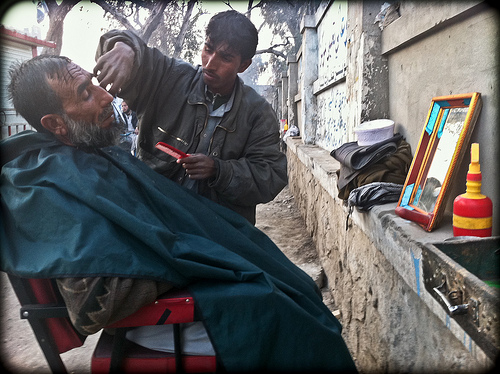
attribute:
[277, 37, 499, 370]
wall — concrete, brick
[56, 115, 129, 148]
beard — gray, black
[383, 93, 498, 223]
mirror — blue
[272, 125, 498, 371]
wall — stone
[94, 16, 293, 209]
man — young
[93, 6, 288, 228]
barber — barbers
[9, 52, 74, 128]
hair — black, wet, trimmed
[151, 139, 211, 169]
comb — small, red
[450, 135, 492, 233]
bottle — yellow, red, striped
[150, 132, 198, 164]
comb — red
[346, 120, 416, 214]
clothes — folded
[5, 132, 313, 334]
blanket — blue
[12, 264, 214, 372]
chair — red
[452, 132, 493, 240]
spray bottle — yellow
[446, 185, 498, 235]
stripes — red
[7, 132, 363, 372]
cape — blue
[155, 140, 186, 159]
comb — red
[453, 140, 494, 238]
sprayer — yellow, red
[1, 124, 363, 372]
sheet — dark teal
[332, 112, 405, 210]
clothes — folded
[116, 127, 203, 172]
comb — red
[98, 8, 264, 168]
man — outdoors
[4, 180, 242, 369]
chair — red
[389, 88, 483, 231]
frame — brown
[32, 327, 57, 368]
metal — black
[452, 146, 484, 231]
bottle — red, yellow, spray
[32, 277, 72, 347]
cushion — red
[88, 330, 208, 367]
cushion — red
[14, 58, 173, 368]
man — older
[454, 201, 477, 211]
stripes — red